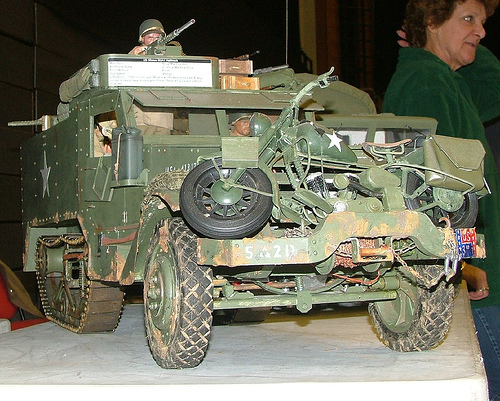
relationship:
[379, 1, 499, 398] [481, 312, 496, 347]
person wearing jeans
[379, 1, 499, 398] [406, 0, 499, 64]
person with hair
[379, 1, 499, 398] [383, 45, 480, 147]
person wearing shirt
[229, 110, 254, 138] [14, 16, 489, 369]
man driving army tank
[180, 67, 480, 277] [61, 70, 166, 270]
bike on machine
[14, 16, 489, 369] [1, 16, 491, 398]
army tank on display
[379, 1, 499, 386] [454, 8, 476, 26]
person has eye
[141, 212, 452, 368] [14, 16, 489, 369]
front wheels of army tank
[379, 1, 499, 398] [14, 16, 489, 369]
person near army tank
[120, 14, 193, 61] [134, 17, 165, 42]
gunner wearing cap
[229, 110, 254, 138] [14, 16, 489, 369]
man inside army tank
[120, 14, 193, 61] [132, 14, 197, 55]
gunner behind gun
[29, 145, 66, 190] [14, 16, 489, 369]
white star on side of army tank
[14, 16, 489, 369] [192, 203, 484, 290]
army tank has bumper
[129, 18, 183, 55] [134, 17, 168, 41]
soldier figurine wearing cap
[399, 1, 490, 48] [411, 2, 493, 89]
hair on caucasian woman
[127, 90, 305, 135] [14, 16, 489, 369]
windshield on army tank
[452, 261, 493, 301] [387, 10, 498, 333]
hand of person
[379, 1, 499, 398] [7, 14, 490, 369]
person standing beside tanker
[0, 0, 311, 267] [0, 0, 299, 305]
wall made of wood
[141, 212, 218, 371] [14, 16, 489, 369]
front wheels on army tank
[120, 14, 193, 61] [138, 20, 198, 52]
gunner holding gun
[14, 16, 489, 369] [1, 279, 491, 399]
army tank in road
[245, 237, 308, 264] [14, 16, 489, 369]
number on army tank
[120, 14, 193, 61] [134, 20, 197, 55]
gunner pointing gun